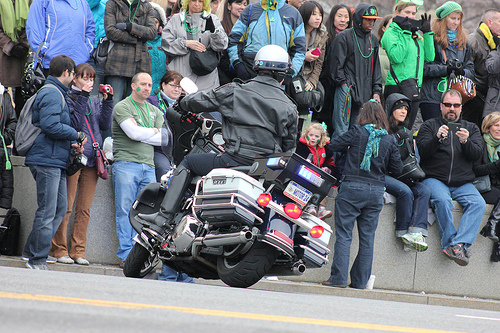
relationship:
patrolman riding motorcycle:
[131, 42, 299, 237] [107, 122, 349, 284]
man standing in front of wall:
[21, 53, 89, 270] [0, 148, 499, 308]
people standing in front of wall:
[61, 61, 114, 267] [0, 148, 499, 308]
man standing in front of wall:
[111, 72, 169, 269] [0, 148, 499, 308]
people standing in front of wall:
[321, 99, 404, 288] [0, 148, 499, 308]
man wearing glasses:
[21, 53, 89, 270] [67, 68, 77, 76]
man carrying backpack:
[21, 53, 89, 270] [16, 71, 34, 143]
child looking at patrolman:
[301, 111, 358, 180] [130, 40, 299, 240]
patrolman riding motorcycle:
[131, 42, 299, 237] [122, 110, 329, 278]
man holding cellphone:
[416, 87, 485, 267] [442, 117, 467, 137]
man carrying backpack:
[21, 53, 89, 270] [13, 92, 46, 160]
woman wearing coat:
[95, 0, 147, 130] [100, 0, 160, 80]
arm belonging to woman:
[102, 0, 138, 44] [95, 0, 147, 130]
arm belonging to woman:
[126, 3, 159, 41] [95, 0, 147, 130]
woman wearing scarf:
[377, 1, 436, 131] [389, 14, 427, 39]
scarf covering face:
[389, 14, 427, 39] [396, 4, 416, 18]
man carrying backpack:
[21, 53, 89, 270] [10, 84, 43, 175]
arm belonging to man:
[112, 103, 157, 143] [111, 72, 167, 271]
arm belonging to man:
[141, 110, 169, 147] [111, 72, 167, 271]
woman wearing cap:
[431, 5, 471, 82] [433, 0, 463, 19]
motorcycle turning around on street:
[125, 32, 340, 283] [1, 264, 483, 329]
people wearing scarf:
[321, 99, 404, 290] [355, 120, 390, 174]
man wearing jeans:
[416, 87, 485, 267] [415, 179, 487, 246]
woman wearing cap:
[418, 0, 474, 122] [433, 0, 463, 19]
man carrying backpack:
[14, 56, 86, 271] [11, 80, 67, 156]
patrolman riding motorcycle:
[131, 42, 299, 237] [127, 106, 365, 270]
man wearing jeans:
[21, 53, 89, 270] [30, 162, 68, 263]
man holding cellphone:
[416, 87, 485, 267] [416, 85, 490, 267]